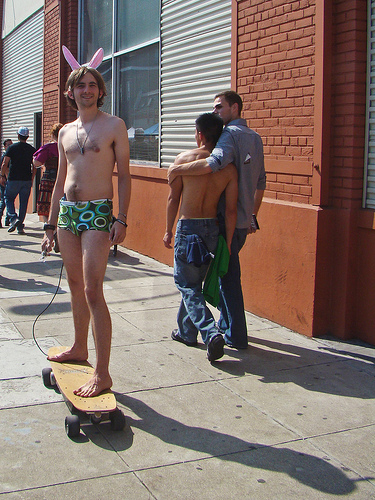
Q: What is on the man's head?
A: Bunny ears.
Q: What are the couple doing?
A: Walking on sidewalk.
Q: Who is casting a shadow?
A: The man.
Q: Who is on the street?
A: A person.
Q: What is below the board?
A: The sidewalk.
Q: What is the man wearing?
A: Pink rabbit ears.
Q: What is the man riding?
A: A board.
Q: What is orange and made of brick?
A: Building.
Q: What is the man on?
A: A skateboard.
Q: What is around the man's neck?
A: A necklace.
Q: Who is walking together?
A: Two guys.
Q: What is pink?
A: The bunny ears.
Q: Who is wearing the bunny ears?
A: The man.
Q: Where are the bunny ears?
A: On the man's head.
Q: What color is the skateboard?
A: Tan.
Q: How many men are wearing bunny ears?
A: One.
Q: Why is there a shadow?
A: The sun.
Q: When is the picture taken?
A: Day time.